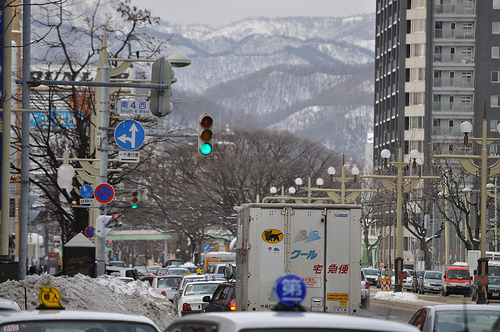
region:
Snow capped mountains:
[228, 16, 364, 133]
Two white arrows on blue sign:
[113, 117, 149, 154]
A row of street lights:
[245, 120, 494, 282]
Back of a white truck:
[229, 185, 372, 322]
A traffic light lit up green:
[181, 105, 232, 167]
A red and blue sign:
[86, 172, 123, 213]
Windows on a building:
[384, 8, 480, 131]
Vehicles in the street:
[378, 240, 479, 309]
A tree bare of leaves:
[156, 132, 341, 233]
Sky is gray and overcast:
[163, 0, 231, 21]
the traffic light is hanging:
[186, 102, 227, 159]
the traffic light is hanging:
[124, 185, 142, 212]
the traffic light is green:
[186, 109, 225, 166]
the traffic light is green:
[131, 179, 148, 218]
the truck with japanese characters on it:
[211, 188, 377, 309]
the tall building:
[361, 3, 499, 236]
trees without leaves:
[147, 147, 339, 205]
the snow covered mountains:
[144, 10, 375, 116]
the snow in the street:
[372, 283, 437, 320]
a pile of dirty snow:
[33, 267, 150, 328]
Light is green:
[199, 141, 211, 156]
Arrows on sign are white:
[116, 120, 143, 146]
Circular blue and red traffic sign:
[92, 180, 115, 201]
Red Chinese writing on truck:
[312, 260, 350, 275]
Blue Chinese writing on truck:
[290, 245, 317, 262]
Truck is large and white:
[235, 196, 362, 318]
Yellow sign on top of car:
[33, 281, 65, 311]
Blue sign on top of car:
[275, 273, 306, 303]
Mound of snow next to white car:
[0, 270, 181, 327]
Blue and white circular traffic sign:
[113, 117, 144, 148]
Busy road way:
[101, 245, 499, 330]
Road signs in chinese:
[83, 86, 150, 226]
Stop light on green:
[190, 97, 230, 177]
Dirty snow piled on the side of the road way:
[6, 270, 183, 327]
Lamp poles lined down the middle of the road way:
[243, 112, 498, 232]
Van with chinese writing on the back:
[238, 202, 363, 317]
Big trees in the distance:
[20, 71, 407, 250]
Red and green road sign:
[473, 265, 492, 290]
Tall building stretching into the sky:
[363, 0, 498, 275]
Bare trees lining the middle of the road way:
[348, 152, 488, 274]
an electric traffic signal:
[199, 111, 214, 156]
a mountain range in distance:
[29, 2, 375, 173]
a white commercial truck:
[236, 204, 363, 309]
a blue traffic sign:
[111, 118, 146, 153]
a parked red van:
[444, 264, 471, 296]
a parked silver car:
[419, 268, 444, 295]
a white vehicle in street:
[175, 281, 217, 317]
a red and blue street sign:
[92, 181, 114, 206]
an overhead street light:
[364, 149, 444, 289]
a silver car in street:
[411, 303, 499, 329]